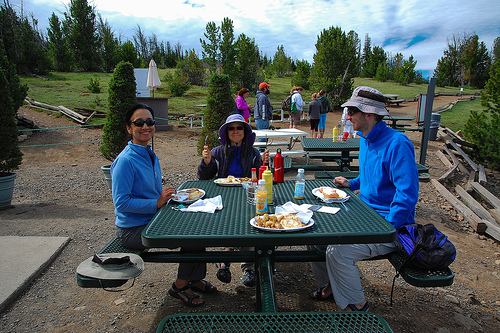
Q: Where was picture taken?
A: At a park.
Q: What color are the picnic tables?
A: Green.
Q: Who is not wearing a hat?
A: A woman.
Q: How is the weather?
A: Cloudy.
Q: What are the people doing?
A: Eating.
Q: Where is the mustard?
A: In the middle of the table.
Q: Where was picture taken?
A: Park.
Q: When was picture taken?
A: During the daytime.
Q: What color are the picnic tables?
A: Green.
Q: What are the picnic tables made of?
A: Metal.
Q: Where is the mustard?
A: In the center of the table.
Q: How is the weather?
A: Cloudy.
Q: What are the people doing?
A: Eating.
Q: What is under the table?
A: Gravel.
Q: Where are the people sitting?
A: Picnic table.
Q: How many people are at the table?
A: Three.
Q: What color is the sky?
A: Blue.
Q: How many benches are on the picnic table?
A: Four.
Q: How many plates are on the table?
A: Four.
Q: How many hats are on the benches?
A: One.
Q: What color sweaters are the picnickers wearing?
A: Blue.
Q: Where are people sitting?
A: At a table.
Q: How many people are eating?
A: Three.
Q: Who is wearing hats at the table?
A: A man and a woman.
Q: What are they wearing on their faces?
A: Sunglasses.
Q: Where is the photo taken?
A: A park.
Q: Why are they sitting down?
A: To eat.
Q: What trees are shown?
A: Evergreens.